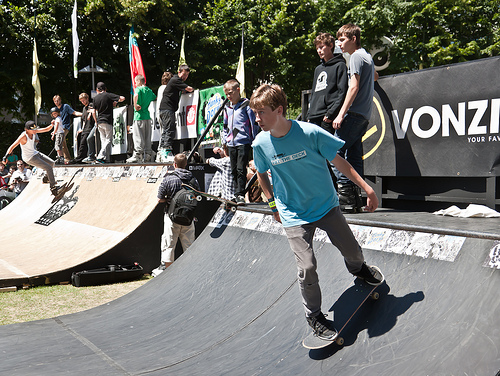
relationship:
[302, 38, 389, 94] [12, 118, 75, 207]
boys watching skateboarders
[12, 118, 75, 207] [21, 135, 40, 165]
skateboarders wearing tank top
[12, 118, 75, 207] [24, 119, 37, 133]
skateboarders wearing cap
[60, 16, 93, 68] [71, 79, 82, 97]
flag on pole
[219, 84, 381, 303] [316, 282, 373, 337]
boy on skateboard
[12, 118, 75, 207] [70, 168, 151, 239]
skateboarders in halfpipe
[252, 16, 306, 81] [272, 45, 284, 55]
tree has leaves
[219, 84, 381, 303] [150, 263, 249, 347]
boy on ramp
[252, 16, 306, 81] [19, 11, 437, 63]
tree on background